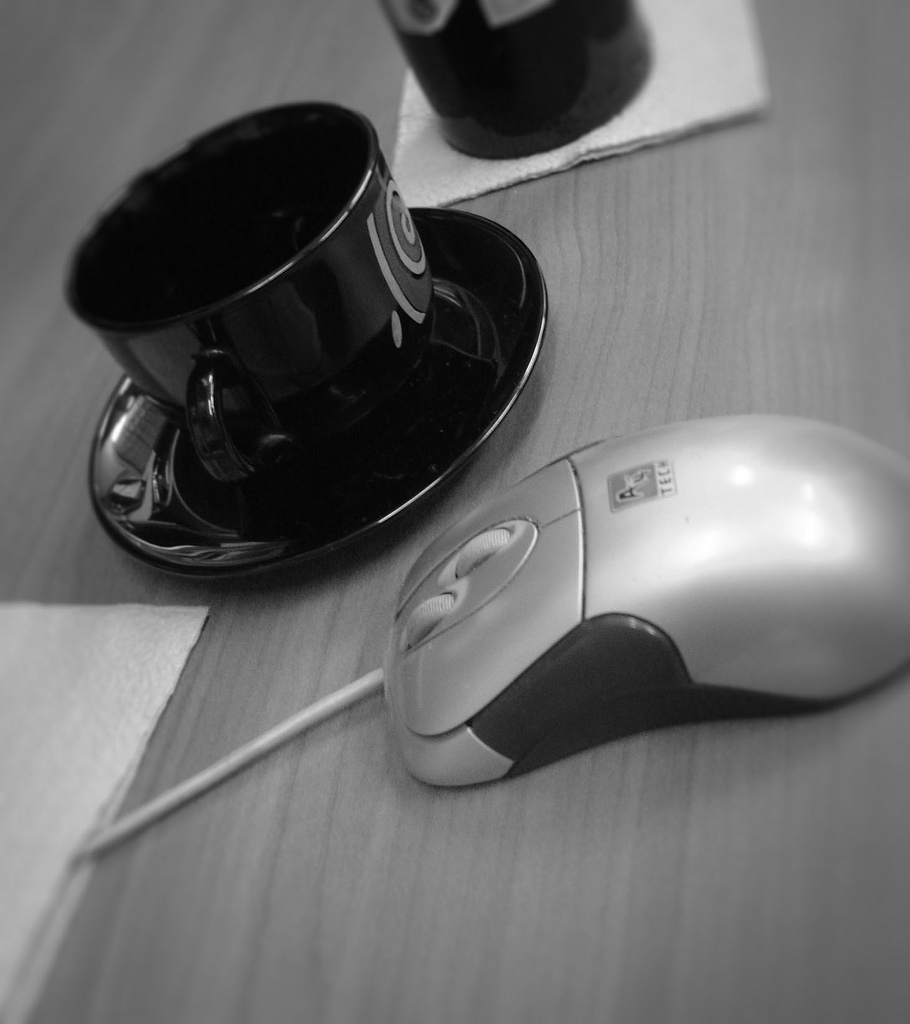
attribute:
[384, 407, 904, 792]
computer mouse — grey, silver, black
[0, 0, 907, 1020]
table — wooden, light colored, wood grain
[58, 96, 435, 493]
cup — black, round, empty, shiny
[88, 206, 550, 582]
saucer — black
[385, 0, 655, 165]
object — black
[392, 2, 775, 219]
napkin — white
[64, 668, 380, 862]
wire connector — white, grey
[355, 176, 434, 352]
design — artistic, bulls-eye, white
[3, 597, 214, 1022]
paper towel — white